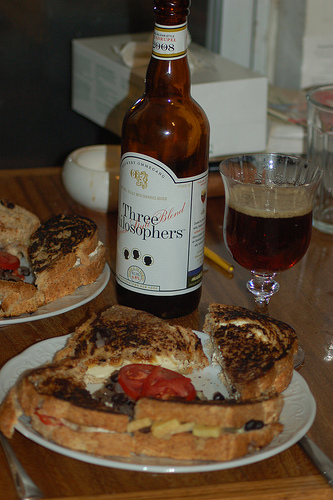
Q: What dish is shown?
A: A sandwich.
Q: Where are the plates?
A: On a table.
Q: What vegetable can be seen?
A: A tomato.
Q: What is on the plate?
A: Food.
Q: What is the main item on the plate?
A: Toasted bread.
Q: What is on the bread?
A: Tomato.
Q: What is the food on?
A: A plate.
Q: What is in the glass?
A: Wine.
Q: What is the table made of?
A: Wood.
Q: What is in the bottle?
A: Wine.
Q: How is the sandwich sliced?
A: Into 4 pieces.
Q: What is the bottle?
A: Beer.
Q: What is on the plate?
A: Sandwich.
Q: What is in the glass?
A: Beer.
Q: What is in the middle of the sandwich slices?
A: Tomato.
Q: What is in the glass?
A: Wine.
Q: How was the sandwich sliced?
A: In 4.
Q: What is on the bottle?
A: White label.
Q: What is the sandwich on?
A: Plate.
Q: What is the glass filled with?
A: Beer.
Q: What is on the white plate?
A: A sandwich.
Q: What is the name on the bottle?
A: Three Philosophers.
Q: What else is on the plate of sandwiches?
A: A tomato.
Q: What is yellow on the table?
A: A colored pencil.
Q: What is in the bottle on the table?
A: Wine.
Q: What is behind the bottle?
A: A white bowl.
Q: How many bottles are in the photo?
A: One.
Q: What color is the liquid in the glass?
A: Brown.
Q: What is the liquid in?
A: Glass.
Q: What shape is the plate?
A: Circle.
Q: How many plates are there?
A: Two.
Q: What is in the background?
A: Kleenex.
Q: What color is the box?
A: White.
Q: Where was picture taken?
A: On a dining table.